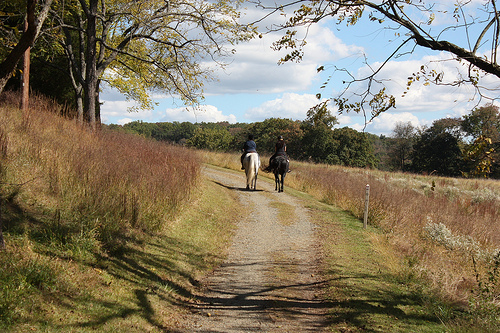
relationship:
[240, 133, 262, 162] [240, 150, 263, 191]
person riding horse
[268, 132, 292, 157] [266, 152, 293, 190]
person riding horse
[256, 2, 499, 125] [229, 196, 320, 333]
tree above trail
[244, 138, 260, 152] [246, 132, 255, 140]
rider wearing helmet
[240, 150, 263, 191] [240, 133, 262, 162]
horse has rider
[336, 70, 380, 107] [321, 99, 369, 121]
branch has leaves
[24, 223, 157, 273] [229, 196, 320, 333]
grass on road